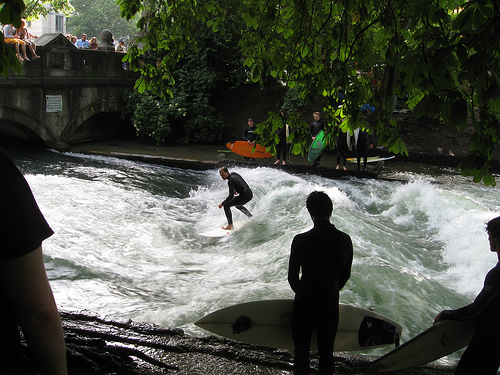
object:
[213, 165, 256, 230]
man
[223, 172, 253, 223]
wetsuit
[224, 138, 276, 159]
surfboard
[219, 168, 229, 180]
head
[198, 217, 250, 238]
surfboard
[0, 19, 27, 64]
onlookers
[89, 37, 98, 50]
onlookers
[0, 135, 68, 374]
bystander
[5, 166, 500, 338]
stream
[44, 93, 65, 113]
sign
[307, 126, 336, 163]
surfboard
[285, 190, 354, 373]
man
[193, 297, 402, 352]
surfboard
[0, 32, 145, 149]
bridge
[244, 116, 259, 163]
man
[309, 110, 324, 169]
man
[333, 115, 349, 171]
man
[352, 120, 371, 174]
man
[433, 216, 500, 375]
man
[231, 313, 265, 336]
design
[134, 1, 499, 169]
trees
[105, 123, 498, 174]
path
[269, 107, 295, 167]
surfers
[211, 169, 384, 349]
waves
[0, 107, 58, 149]
arch